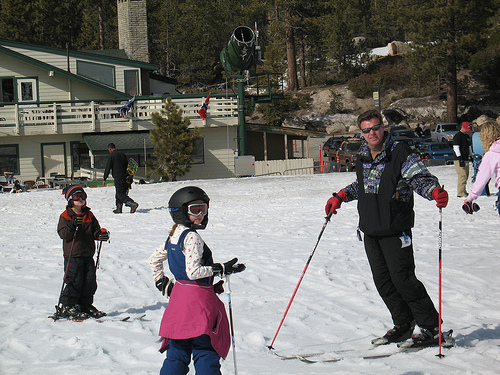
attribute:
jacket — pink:
[156, 279, 232, 359]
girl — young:
[142, 181, 245, 287]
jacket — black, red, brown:
[53, 209, 108, 254]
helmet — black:
[160, 182, 218, 226]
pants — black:
[364, 231, 437, 331]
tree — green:
[72, 0, 112, 49]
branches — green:
[168, 56, 181, 77]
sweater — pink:
[462, 145, 499, 219]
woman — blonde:
[477, 123, 500, 159]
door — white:
[43, 144, 66, 173]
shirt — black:
[101, 153, 129, 182]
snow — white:
[219, 228, 272, 258]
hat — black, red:
[62, 184, 89, 194]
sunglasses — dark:
[357, 123, 385, 134]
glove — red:
[323, 184, 348, 213]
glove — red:
[432, 184, 448, 209]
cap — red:
[462, 121, 471, 133]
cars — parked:
[387, 121, 461, 163]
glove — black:
[213, 254, 250, 277]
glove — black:
[154, 275, 173, 295]